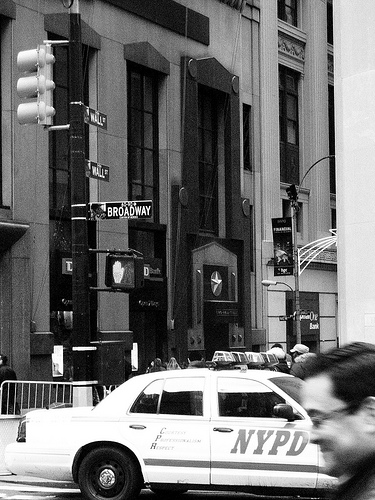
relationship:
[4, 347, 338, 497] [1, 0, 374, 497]
police car belongs to new york city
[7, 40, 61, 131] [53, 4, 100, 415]
traffic light on pole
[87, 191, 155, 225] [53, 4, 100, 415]
street sign on pole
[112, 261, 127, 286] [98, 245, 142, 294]
hand signal on light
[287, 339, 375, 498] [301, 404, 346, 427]
man wearing glasses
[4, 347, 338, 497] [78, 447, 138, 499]
car has a tire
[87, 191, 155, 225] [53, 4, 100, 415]
street sign attached to pole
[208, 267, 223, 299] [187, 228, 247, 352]
star logo on building door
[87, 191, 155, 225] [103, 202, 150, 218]
street sign says broadway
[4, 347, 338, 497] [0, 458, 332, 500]
police car on street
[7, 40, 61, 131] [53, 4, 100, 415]
traffic light attached to pole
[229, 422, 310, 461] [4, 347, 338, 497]
nypd written on car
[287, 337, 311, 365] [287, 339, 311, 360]
man wearing cap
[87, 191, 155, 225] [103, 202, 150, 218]
street sign labeled broadway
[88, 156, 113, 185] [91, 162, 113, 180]
street sign labeled wall st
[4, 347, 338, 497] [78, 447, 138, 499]
car has tire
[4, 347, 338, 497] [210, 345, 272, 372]
police car has emergency lights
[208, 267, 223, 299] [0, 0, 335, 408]
star logo on building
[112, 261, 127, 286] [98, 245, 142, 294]
hand signal on traffic signal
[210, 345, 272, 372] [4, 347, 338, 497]
lights on top of car